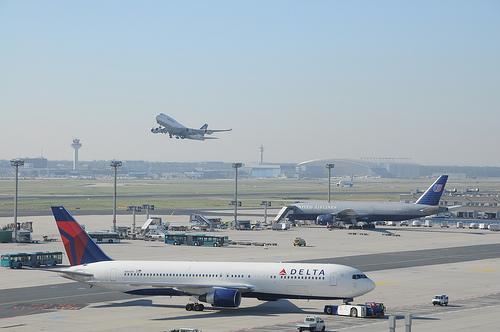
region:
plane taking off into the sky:
[145, 107, 238, 149]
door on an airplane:
[325, 271, 341, 287]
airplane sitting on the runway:
[17, 196, 379, 326]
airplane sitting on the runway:
[280, 171, 465, 231]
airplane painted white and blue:
[17, 197, 387, 314]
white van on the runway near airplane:
[428, 291, 450, 310]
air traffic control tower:
[65, 134, 84, 175]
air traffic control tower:
[254, 136, 269, 169]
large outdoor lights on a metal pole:
[5, 156, 30, 243]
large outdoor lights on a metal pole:
[103, 157, 124, 237]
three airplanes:
[35, 93, 455, 303]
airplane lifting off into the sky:
[148, 106, 235, 154]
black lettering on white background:
[286, 263, 331, 277]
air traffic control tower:
[70, 133, 87, 180]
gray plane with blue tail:
[278, 175, 485, 223]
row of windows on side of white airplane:
[119, 268, 329, 285]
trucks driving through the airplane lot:
[298, 287, 455, 330]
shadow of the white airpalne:
[74, 284, 352, 319]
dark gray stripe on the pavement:
[3, 208, 499, 329]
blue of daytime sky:
[3, 1, 498, 158]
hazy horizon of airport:
[6, 157, 496, 179]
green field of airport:
[1, 177, 489, 212]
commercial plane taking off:
[148, 111, 230, 139]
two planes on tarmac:
[47, 174, 459, 306]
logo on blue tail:
[419, 171, 448, 203]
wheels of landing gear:
[183, 293, 205, 310]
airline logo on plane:
[276, 266, 326, 276]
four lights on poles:
[9, 160, 334, 234]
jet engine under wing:
[142, 280, 252, 305]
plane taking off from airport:
[142, 111, 223, 151]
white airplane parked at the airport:
[43, 200, 370, 318]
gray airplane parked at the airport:
[280, 171, 456, 226]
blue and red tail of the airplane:
[53, 205, 113, 261]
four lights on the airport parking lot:
[7, 149, 339, 247]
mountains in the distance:
[12, 143, 493, 180]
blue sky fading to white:
[5, 10, 497, 176]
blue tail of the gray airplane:
[413, 171, 451, 206]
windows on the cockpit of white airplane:
[348, 266, 370, 285]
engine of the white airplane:
[205, 283, 242, 304]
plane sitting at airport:
[43, 202, 376, 312]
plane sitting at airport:
[275, 175, 457, 215]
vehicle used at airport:
[432, 293, 453, 306]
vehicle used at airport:
[288, 316, 329, 329]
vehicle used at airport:
[360, 299, 385, 316]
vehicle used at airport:
[4, 252, 61, 269]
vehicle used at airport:
[160, 230, 229, 246]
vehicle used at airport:
[293, 230, 308, 250]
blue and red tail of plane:
[45, 195, 110, 268]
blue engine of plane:
[196, 288, 243, 308]